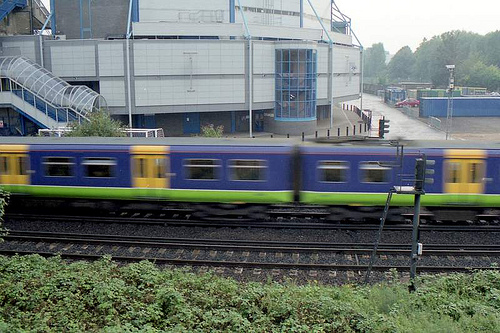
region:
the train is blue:
[160, 120, 356, 240]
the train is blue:
[190, 60, 314, 234]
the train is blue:
[223, 120, 337, 305]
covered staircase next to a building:
[6, 48, 169, 143]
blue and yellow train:
[14, 130, 496, 221]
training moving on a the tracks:
[1, 129, 491, 233]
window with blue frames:
[259, 32, 325, 133]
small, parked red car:
[393, 92, 426, 118]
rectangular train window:
[173, 149, 225, 192]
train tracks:
[134, 229, 394, 282]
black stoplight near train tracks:
[369, 111, 399, 140]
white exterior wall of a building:
[126, 39, 251, 111]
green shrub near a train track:
[25, 243, 228, 329]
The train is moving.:
[0, 130, 499, 220]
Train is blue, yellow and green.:
[1, 135, 499, 216]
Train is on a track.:
[1, 134, 498, 271]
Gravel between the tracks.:
[2, 133, 499, 285]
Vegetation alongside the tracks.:
[1, 237, 498, 331]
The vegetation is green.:
[0, 241, 499, 331]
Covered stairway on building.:
[3, 0, 380, 147]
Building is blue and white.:
[0, 2, 393, 167]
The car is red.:
[390, 90, 427, 113]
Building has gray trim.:
[4, 0, 389, 144]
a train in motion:
[5, 110, 495, 209]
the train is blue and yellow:
[0, 123, 297, 203]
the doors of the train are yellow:
[110, 133, 181, 195]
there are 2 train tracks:
[121, 184, 343, 291]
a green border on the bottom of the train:
[9, 177, 302, 203]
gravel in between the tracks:
[122, 242, 337, 263]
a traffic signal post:
[342, 139, 435, 308]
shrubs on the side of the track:
[0, 247, 391, 325]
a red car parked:
[371, 80, 425, 116]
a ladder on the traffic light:
[356, 173, 406, 281]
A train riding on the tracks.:
[20, 125, 458, 245]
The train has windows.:
[178, 128, 393, 193]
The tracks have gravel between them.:
[146, 226, 429, 273]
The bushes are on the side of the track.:
[68, 277, 320, 322]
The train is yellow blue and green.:
[160, 133, 434, 215]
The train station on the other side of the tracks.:
[112, 1, 405, 145]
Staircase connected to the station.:
[12, 59, 132, 137]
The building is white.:
[104, 14, 376, 124]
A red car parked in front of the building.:
[401, 85, 421, 118]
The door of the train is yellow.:
[138, 146, 175, 191]